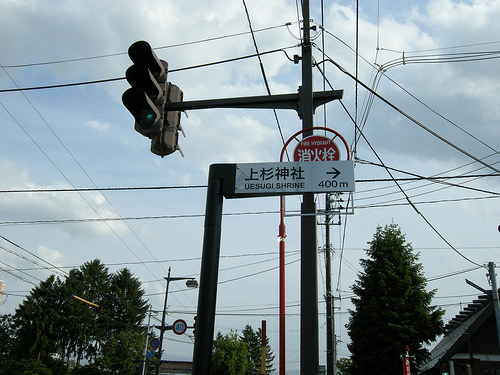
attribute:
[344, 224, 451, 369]
trees — tall, green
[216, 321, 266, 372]
trees — tall, green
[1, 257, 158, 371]
trees — tall, green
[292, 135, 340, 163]
sign — white, red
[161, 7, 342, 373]
pole — black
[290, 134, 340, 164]
sign — red, round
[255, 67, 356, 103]
wall — blue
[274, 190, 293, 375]
pole — red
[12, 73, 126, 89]
line — electrical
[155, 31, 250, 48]
line — electrical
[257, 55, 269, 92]
line — electrical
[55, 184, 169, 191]
line — electrical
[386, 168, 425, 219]
line — electrical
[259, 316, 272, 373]
pole — black, yellow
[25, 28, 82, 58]
building — small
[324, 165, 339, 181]
arrow — black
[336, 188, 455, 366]
tree — evergreen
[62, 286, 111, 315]
guard — yellow, electrical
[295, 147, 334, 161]
sign — red, circle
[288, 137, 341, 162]
sign — orange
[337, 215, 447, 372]
tree — big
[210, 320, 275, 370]
tree — big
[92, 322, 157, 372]
tree — big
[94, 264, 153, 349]
tree — big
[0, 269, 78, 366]
tree — big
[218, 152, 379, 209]
sign — black, white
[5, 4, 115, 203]
clouds — thick, gray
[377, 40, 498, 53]
cable — electrical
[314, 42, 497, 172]
cable — electrical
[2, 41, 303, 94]
cable — electrical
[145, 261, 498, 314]
cable — electrical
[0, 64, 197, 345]
cable — electrical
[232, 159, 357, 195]
sign — white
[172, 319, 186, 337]
sign — metal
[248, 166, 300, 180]
text — Asian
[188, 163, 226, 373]
post — black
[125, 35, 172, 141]
traffic light — green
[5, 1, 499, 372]
sky — gray